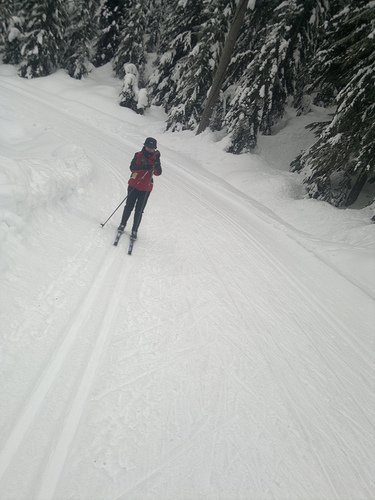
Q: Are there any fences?
A: No, there are no fences.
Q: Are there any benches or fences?
A: No, there are no fences or benches.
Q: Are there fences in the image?
A: No, there are no fences.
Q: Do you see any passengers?
A: No, there are no passengers.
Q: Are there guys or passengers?
A: No, there are no passengers or guys.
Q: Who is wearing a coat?
A: The lady is wearing a coat.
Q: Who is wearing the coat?
A: The lady is wearing a coat.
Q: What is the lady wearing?
A: The lady is wearing a coat.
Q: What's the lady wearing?
A: The lady is wearing a coat.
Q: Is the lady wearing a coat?
A: Yes, the lady is wearing a coat.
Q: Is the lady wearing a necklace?
A: No, the lady is wearing a coat.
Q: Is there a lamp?
A: No, there are no lamps.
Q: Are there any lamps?
A: No, there are no lamps.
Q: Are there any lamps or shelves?
A: No, there are no lamps or shelves.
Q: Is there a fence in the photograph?
A: No, there are no fences.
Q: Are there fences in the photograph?
A: No, there are no fences.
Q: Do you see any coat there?
A: Yes, there is a coat.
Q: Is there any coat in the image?
A: Yes, there is a coat.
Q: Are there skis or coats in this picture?
A: Yes, there is a coat.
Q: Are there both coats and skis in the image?
A: Yes, there are both a coat and skis.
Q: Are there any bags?
A: No, there are no bags.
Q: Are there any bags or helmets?
A: No, there are no bags or helmets.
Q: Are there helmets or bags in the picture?
A: No, there are no bags or helmets.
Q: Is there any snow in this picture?
A: Yes, there is snow.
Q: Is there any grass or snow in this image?
A: Yes, there is snow.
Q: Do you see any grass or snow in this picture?
A: Yes, there is snow.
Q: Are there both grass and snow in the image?
A: No, there is snow but no grass.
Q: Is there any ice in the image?
A: No, there is no ice.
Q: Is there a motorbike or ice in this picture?
A: No, there are no ice or motorcycles.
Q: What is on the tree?
A: The snow is on the tree.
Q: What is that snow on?
A: The snow is on the tree.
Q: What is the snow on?
A: The snow is on the tree.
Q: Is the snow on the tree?
A: Yes, the snow is on the tree.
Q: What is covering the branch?
A: The snow is covering the branch.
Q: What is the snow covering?
A: The snow is covering the branch.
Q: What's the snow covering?
A: The snow is covering the branch.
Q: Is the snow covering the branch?
A: Yes, the snow is covering the branch.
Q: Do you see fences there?
A: No, there are no fences.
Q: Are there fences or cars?
A: No, there are no fences or cars.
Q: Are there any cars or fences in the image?
A: No, there are no fences or cars.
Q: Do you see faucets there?
A: No, there are no faucets.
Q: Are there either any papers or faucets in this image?
A: No, there are no faucets or papers.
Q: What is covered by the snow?
A: The branch is covered by the snow.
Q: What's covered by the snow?
A: The branch is covered by the snow.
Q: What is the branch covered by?
A: The branch is covered by the snow.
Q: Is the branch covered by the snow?
A: Yes, the branch is covered by the snow.